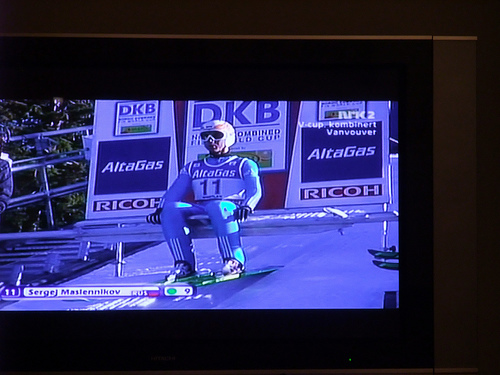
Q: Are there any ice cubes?
A: No, there are no ice cubes.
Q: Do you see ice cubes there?
A: No, there are no ice cubes.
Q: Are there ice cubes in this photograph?
A: No, there are no ice cubes.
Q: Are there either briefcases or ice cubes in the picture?
A: No, there are no ice cubes or briefcases.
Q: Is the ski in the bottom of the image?
A: Yes, the ski is in the bottom of the image.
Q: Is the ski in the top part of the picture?
A: No, the ski is in the bottom of the image.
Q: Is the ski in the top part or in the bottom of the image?
A: The ski is in the bottom of the image.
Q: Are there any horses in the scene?
A: No, there are no horses.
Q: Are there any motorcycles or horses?
A: No, there are no horses or motorcycles.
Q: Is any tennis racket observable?
A: No, there are no rackets.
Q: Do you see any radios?
A: No, there are no radios.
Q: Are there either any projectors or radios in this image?
A: No, there are no radios or projectors.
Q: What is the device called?
A: The device is a screen.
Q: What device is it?
A: The device is a screen.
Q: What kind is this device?
A: This is a screen.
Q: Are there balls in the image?
A: No, there are no balls.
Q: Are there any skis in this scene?
A: Yes, there are skis.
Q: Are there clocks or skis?
A: Yes, there are skis.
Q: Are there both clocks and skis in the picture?
A: No, there are skis but no clocks.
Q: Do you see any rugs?
A: No, there are no rugs.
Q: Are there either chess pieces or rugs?
A: No, there are no rugs or chess pieces.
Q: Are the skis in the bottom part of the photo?
A: Yes, the skis are in the bottom of the image.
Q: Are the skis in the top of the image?
A: No, the skis are in the bottom of the image.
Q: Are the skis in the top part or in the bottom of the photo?
A: The skis are in the bottom of the image.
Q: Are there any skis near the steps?
A: Yes, there are skis near the steps.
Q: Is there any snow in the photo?
A: Yes, there is snow.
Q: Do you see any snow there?
A: Yes, there is snow.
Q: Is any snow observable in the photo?
A: Yes, there is snow.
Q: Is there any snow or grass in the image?
A: Yes, there is snow.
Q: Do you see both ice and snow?
A: No, there is snow but no ice.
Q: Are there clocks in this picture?
A: No, there are no clocks.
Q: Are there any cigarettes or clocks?
A: No, there are no clocks or cigarettes.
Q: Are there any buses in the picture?
A: No, there are no buses.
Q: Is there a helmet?
A: Yes, there is a helmet.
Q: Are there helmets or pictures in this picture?
A: Yes, there is a helmet.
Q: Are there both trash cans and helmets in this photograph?
A: No, there is a helmet but no trash cans.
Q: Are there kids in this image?
A: No, there are no kids.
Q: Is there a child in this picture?
A: No, there are no children.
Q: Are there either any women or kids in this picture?
A: No, there are no kids or women.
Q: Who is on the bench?
A: The man is on the bench.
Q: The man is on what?
A: The man is on the bench.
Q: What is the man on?
A: The man is on the bench.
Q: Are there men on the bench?
A: Yes, there is a man on the bench.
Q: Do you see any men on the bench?
A: Yes, there is a man on the bench.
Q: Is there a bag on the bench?
A: No, there is a man on the bench.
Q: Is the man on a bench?
A: Yes, the man is on a bench.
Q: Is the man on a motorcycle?
A: No, the man is on a bench.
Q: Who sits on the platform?
A: The man sits on the platform.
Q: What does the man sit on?
A: The man sits on the platform.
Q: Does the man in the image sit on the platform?
A: Yes, the man sits on the platform.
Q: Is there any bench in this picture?
A: Yes, there is a bench.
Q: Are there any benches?
A: Yes, there is a bench.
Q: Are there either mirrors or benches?
A: Yes, there is a bench.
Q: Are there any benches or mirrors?
A: Yes, there is a bench.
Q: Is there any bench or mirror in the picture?
A: Yes, there is a bench.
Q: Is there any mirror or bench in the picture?
A: Yes, there is a bench.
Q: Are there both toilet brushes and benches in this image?
A: No, there is a bench but no toilet brushes.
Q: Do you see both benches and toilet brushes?
A: No, there is a bench but no toilet brushes.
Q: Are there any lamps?
A: No, there are no lamps.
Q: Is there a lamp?
A: No, there are no lamps.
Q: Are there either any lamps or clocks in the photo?
A: No, there are no lamps or clocks.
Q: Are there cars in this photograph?
A: No, there are no cars.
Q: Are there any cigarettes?
A: No, there are no cigarettes.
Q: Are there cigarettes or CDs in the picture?
A: No, there are no cigarettes or cds.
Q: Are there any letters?
A: Yes, there are letters.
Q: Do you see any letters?
A: Yes, there are letters.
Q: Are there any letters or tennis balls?
A: Yes, there are letters.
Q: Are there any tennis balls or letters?
A: Yes, there are letters.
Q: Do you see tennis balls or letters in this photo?
A: Yes, there are letters.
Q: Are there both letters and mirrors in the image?
A: No, there are letters but no mirrors.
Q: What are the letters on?
A: The letters are on the sign.